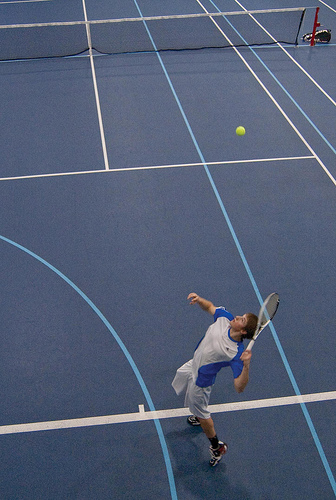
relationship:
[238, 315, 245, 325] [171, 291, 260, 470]
eyes on a man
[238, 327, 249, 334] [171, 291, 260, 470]
ear on man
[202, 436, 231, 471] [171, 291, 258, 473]
foot on player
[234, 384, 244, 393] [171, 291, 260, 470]
elbow on man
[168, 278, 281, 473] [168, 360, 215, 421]
player white shorts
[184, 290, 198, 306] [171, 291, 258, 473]
hand of player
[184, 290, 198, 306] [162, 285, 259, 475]
hand of a man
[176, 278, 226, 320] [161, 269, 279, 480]
arm of a man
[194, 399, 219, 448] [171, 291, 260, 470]
leg of man